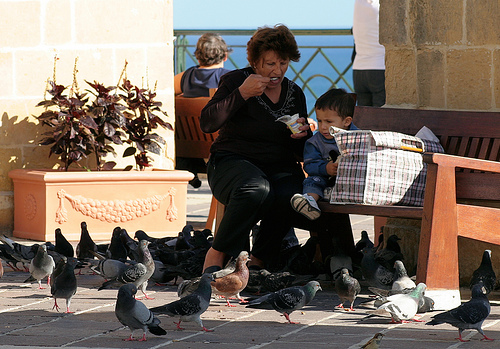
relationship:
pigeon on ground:
[114, 280, 167, 342] [4, 264, 498, 347]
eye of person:
[278, 58, 290, 66] [198, 25, 311, 274]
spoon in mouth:
[269, 74, 276, 77] [248, 57, 311, 98]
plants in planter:
[82, 76, 128, 173] [57, 157, 167, 169]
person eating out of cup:
[198, 25, 311, 274] [275, 114, 307, 135]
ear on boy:
[337, 109, 351, 126] [296, 89, 361, 213]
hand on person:
[239, 74, 267, 99] [198, 25, 311, 274]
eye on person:
[266, 60, 275, 66] [198, 25, 311, 274]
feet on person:
[280, 189, 329, 229] [287, 78, 366, 238]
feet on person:
[289, 194, 326, 220] [203, 24, 317, 278]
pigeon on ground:
[114, 280, 167, 342] [0, 180, 498, 347]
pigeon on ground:
[244, 279, 323, 324] [0, 180, 498, 347]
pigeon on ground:
[330, 265, 361, 312] [0, 180, 498, 347]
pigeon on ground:
[210, 248, 252, 307] [0, 180, 498, 347]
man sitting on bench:
[176, 28, 233, 95] [175, 95, 222, 171]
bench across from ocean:
[175, 95, 222, 171] [172, 32, 354, 133]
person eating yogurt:
[198, 25, 311, 274] [280, 112, 302, 137]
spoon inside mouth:
[269, 74, 276, 77] [269, 70, 284, 85]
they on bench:
[205, 20, 314, 280] [316, 104, 499, 288]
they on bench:
[289, 79, 369, 229] [316, 104, 499, 288]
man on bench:
[180, 31, 233, 99] [175, 91, 226, 166]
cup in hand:
[278, 115, 312, 135] [239, 74, 267, 99]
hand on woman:
[239, 74, 267, 99] [207, 45, 325, 112]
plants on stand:
[33, 50, 175, 173] [8, 165, 195, 243]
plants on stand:
[82, 76, 128, 173] [8, 165, 195, 243]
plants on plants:
[123, 75, 173, 167] [82, 76, 128, 173]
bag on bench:
[338, 125, 425, 207] [423, 112, 495, 287]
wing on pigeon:
[383, 297, 421, 322] [240, 279, 323, 324]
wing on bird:
[216, 270, 245, 300] [354, 275, 444, 335]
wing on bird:
[151, 295, 201, 313] [152, 264, 224, 331]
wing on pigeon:
[258, 290, 307, 313] [210, 254, 252, 307]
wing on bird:
[258, 290, 307, 313] [105, 271, 172, 340]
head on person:
[246, 19, 301, 90] [198, 25, 311, 274]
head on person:
[318, 79, 361, 135] [292, 80, 361, 225]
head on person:
[194, 31, 230, 69] [176, 28, 237, 95]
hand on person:
[239, 74, 267, 99] [195, 22, 350, 322]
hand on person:
[292, 110, 310, 137] [195, 22, 350, 322]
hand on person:
[325, 160, 345, 176] [283, 82, 368, 222]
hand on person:
[292, 110, 310, 137] [289, 73, 367, 223]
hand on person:
[239, 74, 267, 99] [289, 73, 367, 223]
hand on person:
[325, 157, 345, 180] [198, 25, 311, 274]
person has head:
[291, 85, 366, 218] [313, 87, 353, 139]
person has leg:
[198, 25, 311, 274] [202, 160, 271, 275]